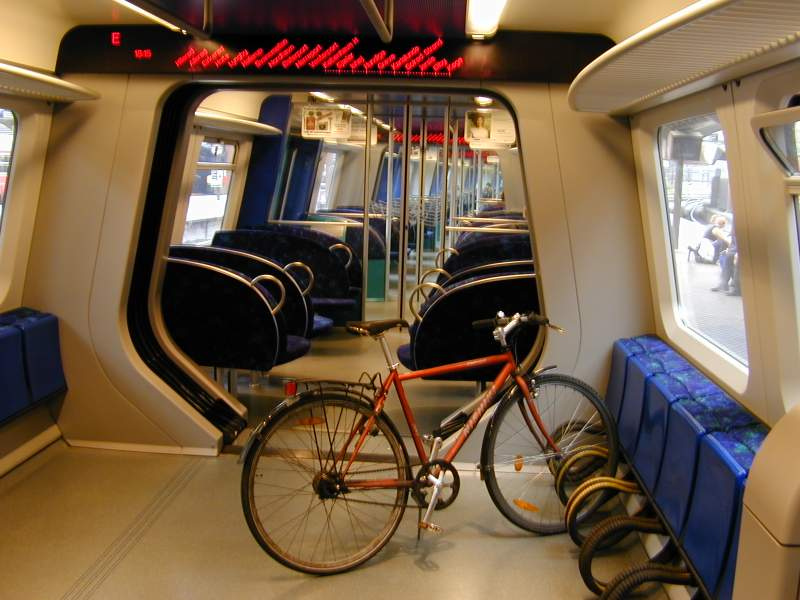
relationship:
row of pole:
[283, 97, 576, 369] [455, 83, 471, 231]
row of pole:
[283, 97, 576, 369] [439, 83, 449, 343]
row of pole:
[283, 97, 576, 369] [402, 83, 419, 343]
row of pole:
[283, 97, 576, 369] [387, 83, 397, 343]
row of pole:
[283, 97, 576, 369] [359, 83, 376, 343]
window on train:
[750, 102, 793, 176] [3, 14, 793, 596]